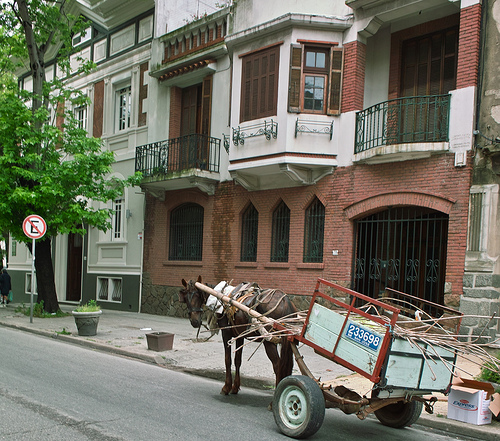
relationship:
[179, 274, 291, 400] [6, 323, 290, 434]
brown horse standing on city street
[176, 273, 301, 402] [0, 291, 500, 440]
brown horse pulling branches on city street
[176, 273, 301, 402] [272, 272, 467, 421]
brown horse attached to a cart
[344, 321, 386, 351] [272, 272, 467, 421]
license plate on cart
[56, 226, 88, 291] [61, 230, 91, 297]
door with insert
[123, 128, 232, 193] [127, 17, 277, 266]
balcony on second floor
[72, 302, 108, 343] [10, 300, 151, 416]
flower pot on city street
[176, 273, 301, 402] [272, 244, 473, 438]
brown horse pulling cart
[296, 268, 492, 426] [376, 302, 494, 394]
cart with tree limbs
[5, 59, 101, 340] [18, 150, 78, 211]
tree with leaves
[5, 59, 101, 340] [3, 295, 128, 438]
tree on city sidewalk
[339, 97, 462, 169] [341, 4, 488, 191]
balcony to a second floor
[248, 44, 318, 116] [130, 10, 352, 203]
windows to a second floor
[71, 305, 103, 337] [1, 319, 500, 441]
flower pot on city sidewalk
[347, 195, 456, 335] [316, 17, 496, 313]
iron gate on building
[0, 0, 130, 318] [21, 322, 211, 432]
tree on sidewalk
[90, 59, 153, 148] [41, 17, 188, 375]
window of a building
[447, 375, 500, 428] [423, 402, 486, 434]
box on sidewalk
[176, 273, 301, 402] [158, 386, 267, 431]
brown horse on street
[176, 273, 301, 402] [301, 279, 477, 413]
brown horse pulling a cart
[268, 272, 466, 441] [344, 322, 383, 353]
cart has license plate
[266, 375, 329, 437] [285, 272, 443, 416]
wheel of cart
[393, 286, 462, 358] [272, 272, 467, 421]
sticks on cart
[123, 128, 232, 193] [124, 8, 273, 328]
balcony in building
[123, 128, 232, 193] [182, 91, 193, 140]
balcony in front of screen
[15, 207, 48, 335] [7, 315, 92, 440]
sign on street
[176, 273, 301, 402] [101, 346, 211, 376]
brown horse at curb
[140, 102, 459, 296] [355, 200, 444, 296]
building with doors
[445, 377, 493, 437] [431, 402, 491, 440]
box on walk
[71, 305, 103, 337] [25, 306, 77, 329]
flower pot on sidewalk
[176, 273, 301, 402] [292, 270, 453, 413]
brown horse with cart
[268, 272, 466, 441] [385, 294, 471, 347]
cart of sticks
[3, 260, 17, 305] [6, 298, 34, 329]
person on sidewalk